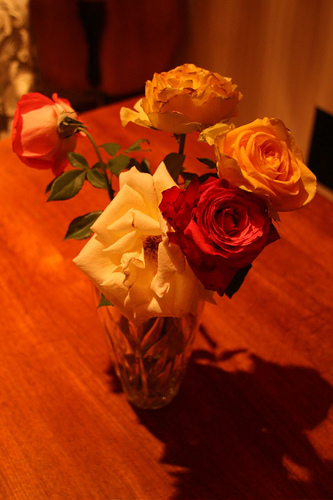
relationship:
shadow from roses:
[102, 347, 331, 499] [10, 62, 317, 327]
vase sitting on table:
[85, 258, 220, 410] [2, 91, 332, 499]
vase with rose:
[90, 279, 205, 410] [75, 66, 279, 317]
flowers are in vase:
[55, 78, 263, 281] [112, 309, 217, 409]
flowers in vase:
[197, 117, 318, 222] [90, 279, 204, 409]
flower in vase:
[119, 62, 242, 132] [90, 279, 204, 409]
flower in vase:
[158, 175, 281, 298] [90, 279, 204, 409]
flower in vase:
[11, 91, 88, 178] [90, 279, 204, 409]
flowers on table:
[88, 128, 255, 319] [19, 375, 117, 475]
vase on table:
[90, 279, 205, 410] [2, 91, 332, 499]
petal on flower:
[154, 86, 191, 109] [101, 50, 236, 145]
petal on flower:
[189, 226, 206, 247] [159, 175, 288, 295]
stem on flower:
[77, 128, 113, 200] [119, 62, 243, 132]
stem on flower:
[178, 129, 185, 153] [10, 91, 80, 175]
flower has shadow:
[9, 53, 321, 322] [102, 347, 331, 499]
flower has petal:
[11, 91, 88, 178] [8, 89, 62, 159]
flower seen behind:
[11, 91, 88, 178] [0, 72, 104, 193]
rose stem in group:
[76, 127, 113, 200] [8, 55, 324, 325]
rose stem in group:
[176, 134, 185, 155] [8, 55, 324, 325]